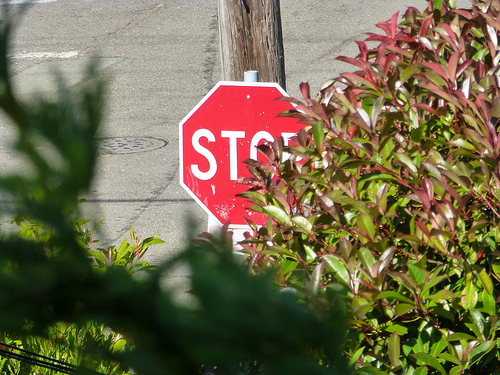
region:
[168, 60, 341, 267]
a red and white stop sign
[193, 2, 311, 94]
a wooden pole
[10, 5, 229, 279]
the road is gray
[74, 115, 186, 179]
a manhole cover in the road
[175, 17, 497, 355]
the sign is partially covered by the bush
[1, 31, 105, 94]
a white line on the road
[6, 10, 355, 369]
the bush is blurry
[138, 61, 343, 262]
the sign says stop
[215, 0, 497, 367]
the leaves are green and auburn colored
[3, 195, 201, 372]
the bush is green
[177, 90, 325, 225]
One board is on sides of the road.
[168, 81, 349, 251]
Stop sign board in pathway.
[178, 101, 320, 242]
Board is red and white color.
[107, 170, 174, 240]
Road is grey color.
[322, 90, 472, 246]
Leaves are green and pink color.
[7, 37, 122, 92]
White lines in road.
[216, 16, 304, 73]
Pole is brown color.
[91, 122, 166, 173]
One man hole cover is on road.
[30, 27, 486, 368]
Day time picture.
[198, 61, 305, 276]
Board is attached to the pole.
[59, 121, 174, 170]
A manhole cover in road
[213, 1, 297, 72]
A wooden electric pole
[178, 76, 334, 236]
A red stop sign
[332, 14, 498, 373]
Green and red bushes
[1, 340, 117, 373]
Three electric lines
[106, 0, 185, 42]
Yellow line in the middle of the road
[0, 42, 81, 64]
White stopping line on road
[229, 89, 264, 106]
Bolt holding stop sign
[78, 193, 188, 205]
Shadow of electric lines on road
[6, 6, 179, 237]
Street with manhole cover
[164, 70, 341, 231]
stop sign behind some plants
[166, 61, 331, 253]
stop sign in front of a wooden post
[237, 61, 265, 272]
the signs metal pole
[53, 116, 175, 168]
a manhole cover in the street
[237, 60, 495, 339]
green plants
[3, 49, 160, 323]
a green tree in the foreground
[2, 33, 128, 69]
white markings on the street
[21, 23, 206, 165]
street corner in the background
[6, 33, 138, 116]
faded pedestrian crossing markings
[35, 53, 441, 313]
Stop Sign Hidden by Bushes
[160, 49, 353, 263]
Stop Sign next to Pole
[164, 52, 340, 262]
Hidden Red Stop Sign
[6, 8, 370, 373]
Deep Shadow Indicates Time of Day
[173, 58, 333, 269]
Stop Sign trimmed in White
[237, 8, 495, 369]
Attractive Bush with Red and Green Leaves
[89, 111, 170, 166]
Manhole Cover in Street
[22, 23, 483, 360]
Hard to See Stop Sign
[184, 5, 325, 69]
Pole made out of Wood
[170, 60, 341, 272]
Bush Covers Part of Common Sign